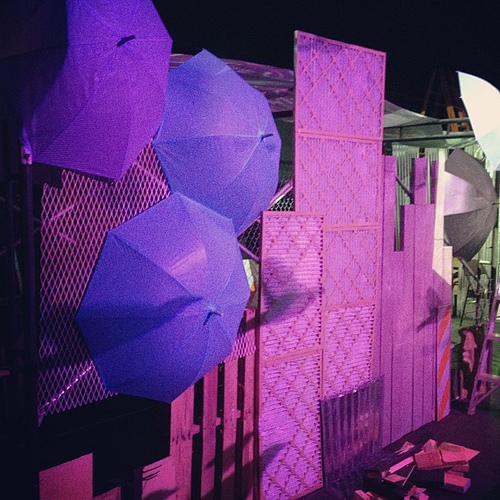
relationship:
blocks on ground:
[354, 435, 480, 497] [239, 294, 475, 489]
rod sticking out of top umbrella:
[205, 302, 223, 325] [114, 203, 323, 424]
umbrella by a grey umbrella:
[446, 150, 499, 262] [442, 147, 496, 264]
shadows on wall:
[203, 440, 288, 499] [0, 90, 455, 498]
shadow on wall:
[199, 431, 291, 498] [0, 90, 455, 498]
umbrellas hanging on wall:
[22, 3, 287, 413] [296, 31, 390, 387]